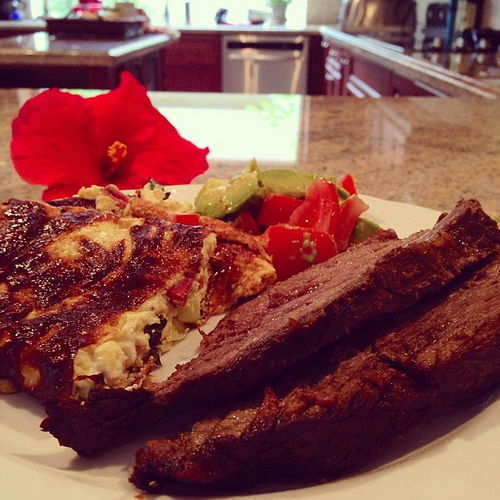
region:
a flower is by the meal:
[19, 70, 209, 208]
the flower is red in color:
[11, 70, 213, 199]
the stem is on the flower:
[104, 140, 126, 177]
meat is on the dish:
[56, 208, 496, 484]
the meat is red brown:
[116, 210, 496, 490]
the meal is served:
[3, 172, 494, 494]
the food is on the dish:
[0, 178, 485, 496]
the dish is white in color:
[2, 179, 493, 497]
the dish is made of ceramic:
[1, 183, 493, 495]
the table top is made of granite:
[0, 88, 498, 498]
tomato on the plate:
[268, 228, 321, 257]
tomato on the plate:
[305, 188, 347, 229]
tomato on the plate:
[261, 195, 288, 221]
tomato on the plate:
[236, 210, 264, 235]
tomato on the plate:
[226, 213, 246, 226]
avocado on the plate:
[212, 183, 256, 208]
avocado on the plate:
[275, 164, 306, 189]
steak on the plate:
[272, 280, 339, 343]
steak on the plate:
[367, 333, 422, 392]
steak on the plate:
[323, 247, 388, 304]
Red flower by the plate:
[7, 68, 210, 205]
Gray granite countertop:
[0, 21, 498, 238]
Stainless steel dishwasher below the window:
[221, 33, 308, 94]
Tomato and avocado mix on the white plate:
[194, 155, 392, 283]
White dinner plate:
[0, 180, 498, 499]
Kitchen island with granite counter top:
[0, 25, 180, 90]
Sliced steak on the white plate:
[42, 196, 498, 494]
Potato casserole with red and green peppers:
[2, 178, 278, 405]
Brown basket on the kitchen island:
[44, 5, 148, 41]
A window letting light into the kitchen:
[31, 0, 306, 23]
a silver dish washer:
[217, 34, 321, 99]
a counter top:
[214, 98, 439, 176]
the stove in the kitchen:
[381, 22, 471, 53]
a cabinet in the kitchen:
[166, 45, 208, 80]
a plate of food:
[19, 185, 449, 497]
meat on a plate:
[50, 243, 481, 426]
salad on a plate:
[211, 173, 339, 239]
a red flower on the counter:
[26, 84, 207, 194]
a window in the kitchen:
[163, 3, 307, 25]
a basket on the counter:
[46, 17, 153, 42]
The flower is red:
[9, 61, 219, 224]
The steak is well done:
[66, 183, 499, 458]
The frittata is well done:
[8, 187, 273, 413]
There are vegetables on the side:
[174, 146, 401, 270]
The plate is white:
[3, 160, 495, 492]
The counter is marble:
[8, 79, 495, 287]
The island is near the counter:
[0, 12, 190, 73]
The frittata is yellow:
[3, 179, 268, 403]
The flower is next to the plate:
[5, 74, 491, 494]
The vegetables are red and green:
[186, 145, 403, 287]